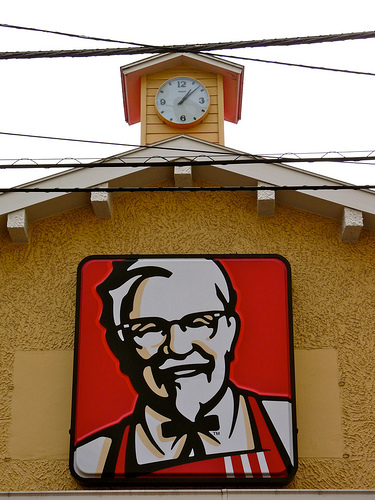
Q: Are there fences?
A: No, there are no fences.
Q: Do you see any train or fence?
A: No, there are no fences or trains.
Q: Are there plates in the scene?
A: No, there are no plates.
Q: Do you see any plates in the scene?
A: No, there are no plates.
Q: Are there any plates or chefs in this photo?
A: No, there are no plates or chefs.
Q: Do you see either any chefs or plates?
A: No, there are no plates or chefs.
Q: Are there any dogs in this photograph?
A: No, there are no dogs.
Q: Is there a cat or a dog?
A: No, there are no dogs or cats.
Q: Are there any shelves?
A: No, there are no shelves.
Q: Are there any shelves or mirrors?
A: No, there are no shelves or mirrors.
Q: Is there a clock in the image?
A: Yes, there is a clock.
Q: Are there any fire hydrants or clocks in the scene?
A: Yes, there is a clock.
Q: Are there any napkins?
A: No, there are no napkins.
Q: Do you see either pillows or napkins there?
A: No, there are no napkins or pillows.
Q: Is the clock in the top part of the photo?
A: Yes, the clock is in the top of the image.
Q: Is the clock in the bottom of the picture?
A: No, the clock is in the top of the image.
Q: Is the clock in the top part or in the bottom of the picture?
A: The clock is in the top of the image.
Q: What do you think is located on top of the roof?
A: The clock is on top of the roof.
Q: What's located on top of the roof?
A: The clock is on top of the roof.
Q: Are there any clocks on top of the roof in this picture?
A: Yes, there is a clock on top of the roof.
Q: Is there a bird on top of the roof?
A: No, there is a clock on top of the roof.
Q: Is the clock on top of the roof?
A: Yes, the clock is on top of the roof.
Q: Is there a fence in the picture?
A: No, there are no fences.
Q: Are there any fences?
A: No, there are no fences.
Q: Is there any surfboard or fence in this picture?
A: No, there are no fences or surfboards.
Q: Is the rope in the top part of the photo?
A: Yes, the rope is in the top of the image.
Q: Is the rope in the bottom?
A: No, the rope is in the top of the image.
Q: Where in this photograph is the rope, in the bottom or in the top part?
A: The rope is in the top of the image.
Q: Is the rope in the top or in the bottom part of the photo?
A: The rope is in the top of the image.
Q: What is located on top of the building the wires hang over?
A: The rope is on top of the building.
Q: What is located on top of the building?
A: The rope is on top of the building.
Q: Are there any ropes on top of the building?
A: Yes, there is a rope on top of the building.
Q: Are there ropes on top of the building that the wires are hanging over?
A: Yes, there is a rope on top of the building.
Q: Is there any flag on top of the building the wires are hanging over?
A: No, there is a rope on top of the building.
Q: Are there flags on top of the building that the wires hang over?
A: No, there is a rope on top of the building.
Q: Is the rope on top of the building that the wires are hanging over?
A: Yes, the rope is on top of the building.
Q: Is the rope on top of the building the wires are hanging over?
A: Yes, the rope is on top of the building.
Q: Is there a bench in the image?
A: No, there are no benches.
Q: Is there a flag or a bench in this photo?
A: No, there are no benches or flags.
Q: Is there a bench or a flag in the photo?
A: No, there are no benches or flags.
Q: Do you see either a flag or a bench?
A: No, there are no benches or flags.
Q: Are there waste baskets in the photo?
A: No, there are no waste baskets.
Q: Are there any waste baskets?
A: No, there are no waste baskets.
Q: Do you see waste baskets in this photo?
A: No, there are no waste baskets.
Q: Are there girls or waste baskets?
A: No, there are no waste baskets or girls.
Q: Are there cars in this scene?
A: No, there are no cars.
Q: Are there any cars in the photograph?
A: No, there are no cars.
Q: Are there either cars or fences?
A: No, there are no cars or fences.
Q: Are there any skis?
A: No, there are no skis.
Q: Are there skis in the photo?
A: No, there are no skis.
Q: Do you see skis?
A: No, there are no skis.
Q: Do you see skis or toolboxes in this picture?
A: No, there are no skis or toolboxes.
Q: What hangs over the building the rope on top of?
A: The wires hang over the building.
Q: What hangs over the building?
A: The wires hang over the building.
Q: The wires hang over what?
A: The wires hang over the building.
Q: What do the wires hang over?
A: The wires hang over the building.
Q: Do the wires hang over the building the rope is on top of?
A: Yes, the wires hang over the building.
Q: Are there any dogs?
A: No, there are no dogs.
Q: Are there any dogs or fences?
A: No, there are no dogs or fences.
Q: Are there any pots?
A: No, there are no pots.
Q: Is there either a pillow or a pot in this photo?
A: No, there are no pots or pillows.